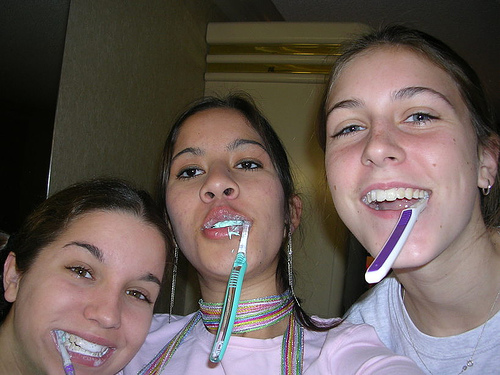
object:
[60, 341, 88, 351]
teeth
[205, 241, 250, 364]
toothbrush handle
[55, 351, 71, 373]
toothbrush handle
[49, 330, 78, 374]
toothbrush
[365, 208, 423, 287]
handle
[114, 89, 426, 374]
girl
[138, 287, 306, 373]
scarf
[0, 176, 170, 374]
girl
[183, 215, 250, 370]
toothbrush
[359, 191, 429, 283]
toothbrush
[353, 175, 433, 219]
mouth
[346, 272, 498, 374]
shirt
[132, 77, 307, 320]
hair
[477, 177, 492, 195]
black earrings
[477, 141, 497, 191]
ear